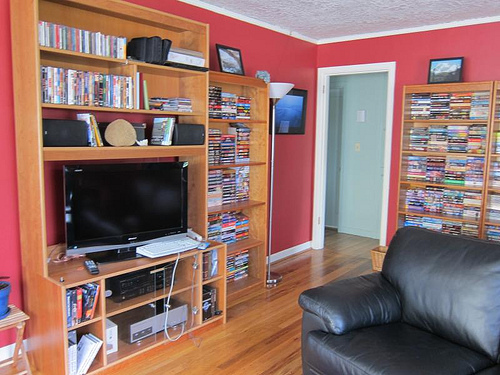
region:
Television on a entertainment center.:
[57, 156, 192, 256]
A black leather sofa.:
[295, 225, 495, 370]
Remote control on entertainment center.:
[80, 255, 105, 275]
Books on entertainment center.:
[206, 81, 266, 256]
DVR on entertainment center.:
[117, 290, 202, 350]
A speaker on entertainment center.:
[42, 115, 100, 150]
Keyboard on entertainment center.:
[135, 232, 205, 260]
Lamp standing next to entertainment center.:
[264, 79, 292, 291]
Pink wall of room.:
[276, 143, 310, 238]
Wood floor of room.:
[238, 295, 295, 366]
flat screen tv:
[43, 166, 190, 252]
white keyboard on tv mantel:
[137, 225, 219, 262]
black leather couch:
[299, 247, 499, 373]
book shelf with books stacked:
[404, 84, 499, 238]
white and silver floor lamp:
[262, 79, 296, 296]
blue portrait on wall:
[272, 82, 317, 145]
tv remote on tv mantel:
[77, 249, 112, 289]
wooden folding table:
[2, 290, 39, 373]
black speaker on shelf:
[37, 112, 95, 154]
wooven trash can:
[368, 235, 393, 276]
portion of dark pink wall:
[272, 47, 308, 72]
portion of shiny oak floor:
[169, 331, 284, 353]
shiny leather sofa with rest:
[307, 221, 484, 366]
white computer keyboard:
[141, 234, 210, 259]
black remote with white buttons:
[75, 256, 109, 282]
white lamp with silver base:
[268, 80, 297, 296]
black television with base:
[47, 153, 195, 264]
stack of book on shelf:
[33, 14, 143, 59]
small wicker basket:
[359, 238, 399, 277]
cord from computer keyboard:
[158, 254, 196, 352]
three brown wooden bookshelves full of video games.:
[196, 0, 498, 302]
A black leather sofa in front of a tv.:
[301, 227, 498, 374]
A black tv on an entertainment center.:
[57, 161, 187, 266]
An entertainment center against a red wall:
[11, 1, 228, 373]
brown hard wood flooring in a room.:
[1, 227, 382, 374]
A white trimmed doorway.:
[311, 60, 392, 251]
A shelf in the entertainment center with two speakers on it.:
[39, 117, 206, 161]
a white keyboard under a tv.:
[135, 232, 206, 257]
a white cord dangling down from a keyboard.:
[163, 248, 186, 343]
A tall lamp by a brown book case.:
[262, 80, 293, 283]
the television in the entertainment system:
[62, 172, 190, 248]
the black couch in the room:
[302, 258, 497, 347]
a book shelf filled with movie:
[400, 93, 482, 235]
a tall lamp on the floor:
[264, 77, 287, 291]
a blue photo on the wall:
[272, 85, 310, 137]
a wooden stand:
[0, 303, 34, 373]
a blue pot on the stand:
[2, 277, 17, 316]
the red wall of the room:
[252, 29, 314, 77]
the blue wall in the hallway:
[332, 78, 379, 249]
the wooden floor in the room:
[234, 302, 298, 363]